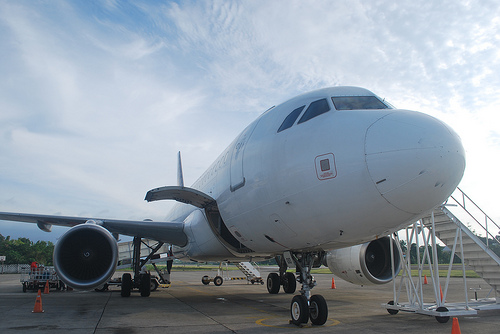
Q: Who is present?
A: No one.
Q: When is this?
A: Daytime.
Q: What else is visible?
A: Wheels.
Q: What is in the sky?
A: Clouds.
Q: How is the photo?
A: Clear.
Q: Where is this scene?
A: At an airport.